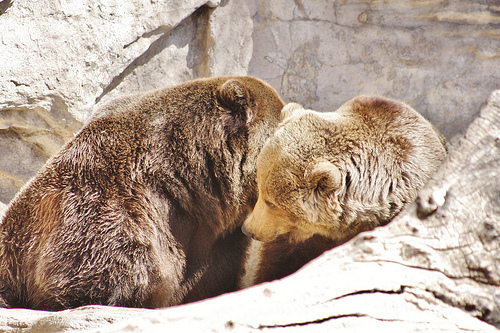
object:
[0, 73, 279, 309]
skin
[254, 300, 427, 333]
mark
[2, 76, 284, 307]
animal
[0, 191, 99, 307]
fur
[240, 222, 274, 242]
mouth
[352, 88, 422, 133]
hump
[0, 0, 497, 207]
wall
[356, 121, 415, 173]
fur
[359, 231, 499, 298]
area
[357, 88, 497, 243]
edge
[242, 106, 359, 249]
head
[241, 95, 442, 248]
bear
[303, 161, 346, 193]
ear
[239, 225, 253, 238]
nose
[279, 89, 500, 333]
tree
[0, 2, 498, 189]
rock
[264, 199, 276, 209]
eye